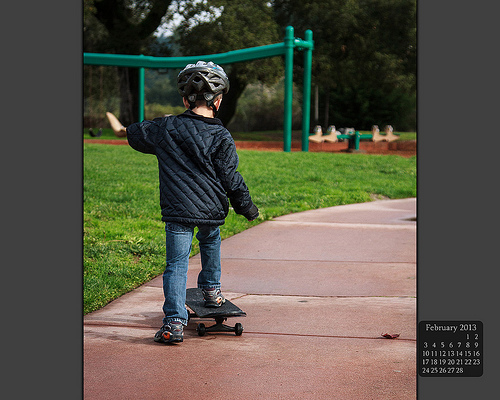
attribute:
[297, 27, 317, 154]
pole — green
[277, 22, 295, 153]
pole — green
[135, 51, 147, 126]
pole — green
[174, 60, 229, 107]
helmet — black 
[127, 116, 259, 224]
jacket — black , wrinkled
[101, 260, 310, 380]
shoe — tennis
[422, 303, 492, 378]
calendar — February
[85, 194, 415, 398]
wet sidewalk — concrete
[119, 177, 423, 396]
pavement — damp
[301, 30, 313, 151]
pole — green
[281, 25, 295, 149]
pole — green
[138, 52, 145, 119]
pole — green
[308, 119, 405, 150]
see saw — green 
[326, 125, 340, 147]
seat — brown 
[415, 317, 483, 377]
calendar — custom-made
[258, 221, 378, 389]
ground — pavement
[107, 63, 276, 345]
boy — little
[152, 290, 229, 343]
shoe — black , red 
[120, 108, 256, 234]
coat — black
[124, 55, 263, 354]
boy — young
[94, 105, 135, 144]
hand — outstreched